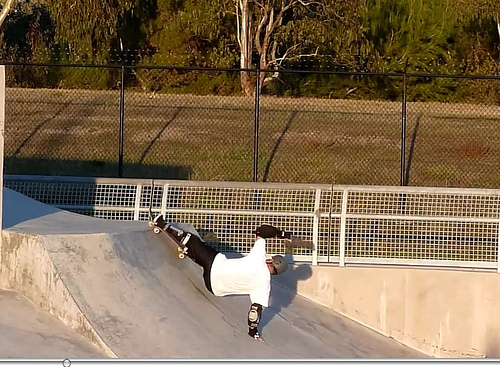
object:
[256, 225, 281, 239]
band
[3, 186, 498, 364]
ground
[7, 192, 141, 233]
deck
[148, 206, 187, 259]
skateboard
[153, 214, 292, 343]
woman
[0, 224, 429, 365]
ramp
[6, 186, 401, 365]
concrete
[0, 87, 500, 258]
ground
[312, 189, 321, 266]
pole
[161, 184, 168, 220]
pole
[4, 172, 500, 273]
fence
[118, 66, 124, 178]
pole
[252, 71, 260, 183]
pole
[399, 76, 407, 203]
pole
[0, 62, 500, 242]
fence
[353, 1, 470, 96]
tree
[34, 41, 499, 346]
park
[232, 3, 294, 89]
trunk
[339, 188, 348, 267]
pole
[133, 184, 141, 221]
pole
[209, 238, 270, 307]
shirt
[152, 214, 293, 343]
man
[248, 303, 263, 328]
arm pad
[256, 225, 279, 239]
arm pad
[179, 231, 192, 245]
knee pad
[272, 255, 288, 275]
helmet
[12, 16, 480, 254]
background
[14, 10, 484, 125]
distance